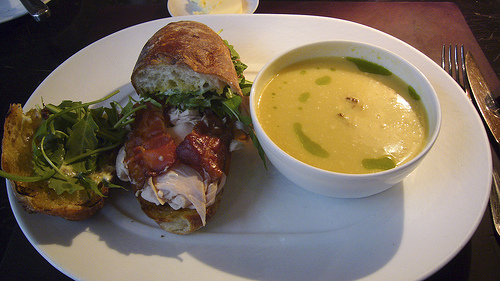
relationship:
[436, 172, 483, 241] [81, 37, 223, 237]
plate with sandwhich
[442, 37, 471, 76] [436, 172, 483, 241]
fork near plate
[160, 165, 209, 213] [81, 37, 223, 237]
meat on sandwhich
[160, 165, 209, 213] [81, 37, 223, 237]
meat in sandwhich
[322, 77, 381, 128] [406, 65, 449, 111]
soup in bowl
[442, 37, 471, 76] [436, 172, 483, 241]
fork under plate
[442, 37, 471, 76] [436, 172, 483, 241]
fork on plate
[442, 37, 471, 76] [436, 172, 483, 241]
fork next to plate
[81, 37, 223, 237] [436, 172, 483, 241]
sandwhich on plate